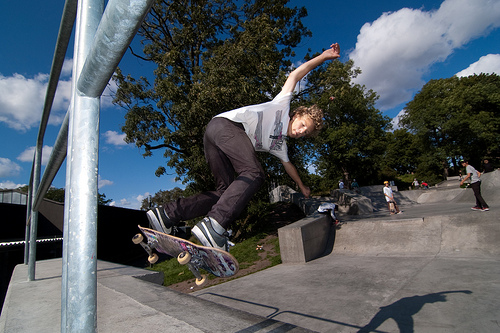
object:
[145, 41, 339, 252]
boy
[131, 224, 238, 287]
skateboard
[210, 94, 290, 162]
shirt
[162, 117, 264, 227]
black jeans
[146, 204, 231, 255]
tennis shoes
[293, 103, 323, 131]
blonde hair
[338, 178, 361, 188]
spectators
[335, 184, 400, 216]
ramp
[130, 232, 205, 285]
four wheels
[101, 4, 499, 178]
trees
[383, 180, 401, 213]
boy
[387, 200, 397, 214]
skateboard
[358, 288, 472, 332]
shadow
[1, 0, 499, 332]
air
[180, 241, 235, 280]
pictures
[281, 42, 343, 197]
arms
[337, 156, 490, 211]
peaple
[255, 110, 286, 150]
gray stripes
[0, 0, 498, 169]
sky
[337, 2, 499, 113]
clouds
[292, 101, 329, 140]
helmet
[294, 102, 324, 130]
worn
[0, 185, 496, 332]
ground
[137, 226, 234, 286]
underside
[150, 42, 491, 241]
kids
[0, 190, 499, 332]
skatepark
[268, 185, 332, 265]
cement wall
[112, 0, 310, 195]
tree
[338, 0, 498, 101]
formation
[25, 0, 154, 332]
fence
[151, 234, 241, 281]
patch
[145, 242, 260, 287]
grass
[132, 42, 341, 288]
skateboard trick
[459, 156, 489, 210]
person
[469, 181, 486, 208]
dark pants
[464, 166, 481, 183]
white shirt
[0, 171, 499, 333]
cement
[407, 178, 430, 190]
people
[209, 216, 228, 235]
white socks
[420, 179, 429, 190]
person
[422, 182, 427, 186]
red shirt